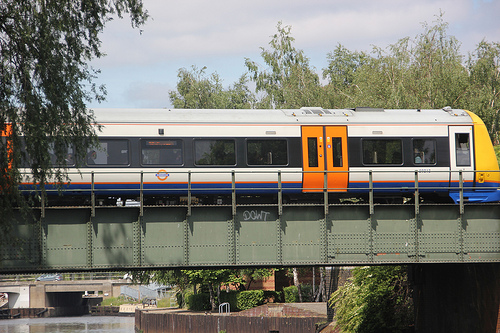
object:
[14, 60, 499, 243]
train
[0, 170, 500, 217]
safety rail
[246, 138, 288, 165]
window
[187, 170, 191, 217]
rail post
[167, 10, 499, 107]
tree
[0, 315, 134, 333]
river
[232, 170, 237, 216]
post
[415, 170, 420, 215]
post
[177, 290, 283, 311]
bushes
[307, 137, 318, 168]
window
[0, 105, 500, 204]
passenger train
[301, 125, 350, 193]
yellow doors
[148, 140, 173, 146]
electric display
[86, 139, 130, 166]
window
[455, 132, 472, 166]
window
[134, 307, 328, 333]
river embankment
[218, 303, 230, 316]
ladder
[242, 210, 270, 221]
graffiti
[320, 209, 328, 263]
steel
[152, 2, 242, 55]
sky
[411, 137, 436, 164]
window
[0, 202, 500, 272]
bridge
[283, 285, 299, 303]
shubberies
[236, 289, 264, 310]
shubberies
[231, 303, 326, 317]
path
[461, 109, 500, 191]
end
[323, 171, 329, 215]
rail post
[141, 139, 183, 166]
window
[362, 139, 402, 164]
window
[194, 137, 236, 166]
window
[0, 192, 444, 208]
rail post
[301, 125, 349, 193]
doors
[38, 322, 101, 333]
water